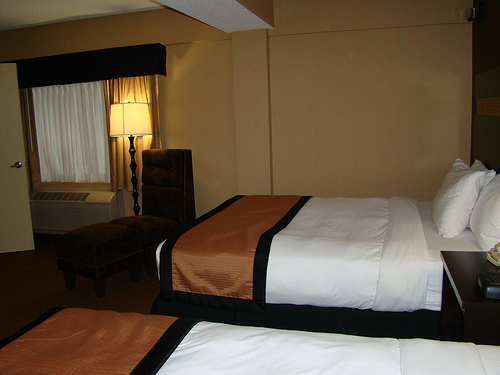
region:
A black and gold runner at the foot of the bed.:
[163, 187, 315, 312]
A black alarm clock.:
[476, 269, 498, 297]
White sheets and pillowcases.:
[154, 155, 496, 308]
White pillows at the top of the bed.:
[431, 159, 498, 252]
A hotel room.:
[4, 5, 498, 372]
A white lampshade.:
[106, 99, 153, 137]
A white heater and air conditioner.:
[34, 188, 119, 237]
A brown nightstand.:
[437, 251, 498, 343]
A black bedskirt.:
[153, 301, 453, 339]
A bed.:
[157, 193, 489, 349]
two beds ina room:
[23, 86, 497, 336]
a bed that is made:
[21, 79, 499, 334]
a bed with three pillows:
[162, 66, 498, 328]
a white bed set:
[152, 108, 499, 332]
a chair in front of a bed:
[24, 122, 247, 296]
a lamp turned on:
[64, 78, 216, 278]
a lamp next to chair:
[27, 45, 271, 307]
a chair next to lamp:
[24, 66, 246, 298]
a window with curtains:
[4, 34, 208, 221]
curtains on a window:
[10, 50, 211, 218]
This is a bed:
[155, 158, 497, 348]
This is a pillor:
[429, 152, 474, 239]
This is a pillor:
[472, 174, 498, 262]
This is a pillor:
[463, 146, 498, 189]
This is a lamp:
[102, 90, 156, 230]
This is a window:
[13, 62, 160, 208]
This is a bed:
[20, 304, 497, 374]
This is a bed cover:
[160, 159, 312, 319]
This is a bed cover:
[0, 301, 200, 372]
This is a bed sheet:
[300, 179, 433, 324]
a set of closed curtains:
[19, 81, 161, 195]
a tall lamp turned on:
[105, 105, 150, 221]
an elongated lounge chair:
[58, 145, 197, 297]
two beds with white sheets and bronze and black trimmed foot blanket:
[1, 157, 498, 374]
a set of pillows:
[432, 156, 499, 253]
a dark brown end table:
[437, 246, 499, 338]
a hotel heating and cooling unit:
[29, 185, 125, 235]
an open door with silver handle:
[2, 60, 39, 253]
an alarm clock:
[475, 268, 499, 300]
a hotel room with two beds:
[1, 0, 499, 373]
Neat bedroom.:
[3, 1, 498, 366]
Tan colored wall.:
[192, 35, 437, 185]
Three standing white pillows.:
[427, 155, 497, 240]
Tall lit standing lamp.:
[105, 96, 152, 216]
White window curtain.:
[30, 77, 110, 182]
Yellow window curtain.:
[107, 72, 157, 190]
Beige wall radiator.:
[30, 185, 128, 232]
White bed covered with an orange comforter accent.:
[160, 190, 431, 311]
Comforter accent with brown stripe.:
[155, 190, 310, 310]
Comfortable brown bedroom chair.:
[53, 146, 196, 291]